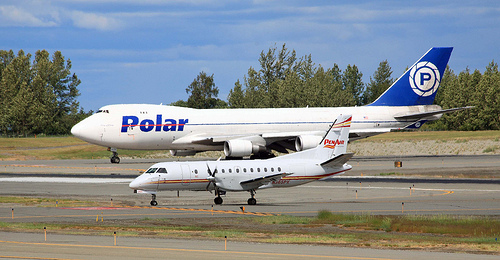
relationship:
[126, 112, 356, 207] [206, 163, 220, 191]
airplane has propeller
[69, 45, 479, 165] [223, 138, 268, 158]
airplane has jet engine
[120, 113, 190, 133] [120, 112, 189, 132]
logo says polar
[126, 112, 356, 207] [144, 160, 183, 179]
airplane has cockpit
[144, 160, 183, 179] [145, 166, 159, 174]
cockpit has window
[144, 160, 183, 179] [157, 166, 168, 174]
cockpit has window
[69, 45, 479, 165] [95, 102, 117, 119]
airplane has cockpit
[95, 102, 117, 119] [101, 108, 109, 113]
cockpit has window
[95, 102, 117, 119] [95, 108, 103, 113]
cockpit has window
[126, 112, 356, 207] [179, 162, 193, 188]
airplane has door hatch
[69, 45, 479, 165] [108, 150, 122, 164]
airplane has landing gear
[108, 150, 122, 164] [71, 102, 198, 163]
landing gear on front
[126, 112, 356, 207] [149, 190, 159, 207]
airplane has landing gear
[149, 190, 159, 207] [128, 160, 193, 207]
landing gear on front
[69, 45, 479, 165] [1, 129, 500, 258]
airplane on ground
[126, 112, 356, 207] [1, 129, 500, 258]
airplane on ground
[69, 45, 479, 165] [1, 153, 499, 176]
airplane on runway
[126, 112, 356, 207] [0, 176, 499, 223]
airplane on runway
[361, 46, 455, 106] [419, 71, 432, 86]
tail has letter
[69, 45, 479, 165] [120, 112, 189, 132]
airplane says polar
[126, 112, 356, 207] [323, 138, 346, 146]
airplane has writing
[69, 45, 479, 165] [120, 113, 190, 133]
airplane has logo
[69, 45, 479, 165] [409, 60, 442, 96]
airplane hs design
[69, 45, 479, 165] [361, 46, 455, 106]
airplane has tail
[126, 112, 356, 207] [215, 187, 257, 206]
airplane has landing gear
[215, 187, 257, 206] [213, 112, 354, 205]
landing gear on back